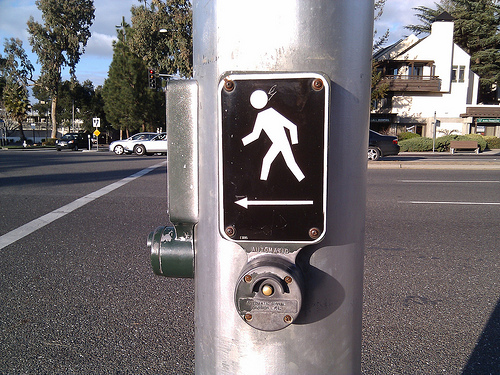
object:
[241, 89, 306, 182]
figure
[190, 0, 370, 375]
pole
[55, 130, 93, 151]
car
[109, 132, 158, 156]
car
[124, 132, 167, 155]
car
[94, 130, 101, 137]
traffic sign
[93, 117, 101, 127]
traffic sign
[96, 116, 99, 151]
pole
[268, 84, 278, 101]
writing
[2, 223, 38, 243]
paint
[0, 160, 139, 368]
ground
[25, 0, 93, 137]
trees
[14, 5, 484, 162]
back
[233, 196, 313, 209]
arrow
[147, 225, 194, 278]
light switch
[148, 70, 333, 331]
traffic equipment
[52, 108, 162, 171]
traffic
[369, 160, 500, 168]
curb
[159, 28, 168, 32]
street light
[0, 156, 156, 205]
area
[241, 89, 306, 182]
symbol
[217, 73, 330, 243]
crosswalk sign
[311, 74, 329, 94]
screw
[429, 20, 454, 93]
chimney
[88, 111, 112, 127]
road sign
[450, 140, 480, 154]
bench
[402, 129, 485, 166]
bus stop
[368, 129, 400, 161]
cars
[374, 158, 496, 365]
street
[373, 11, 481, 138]
house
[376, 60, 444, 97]
balcony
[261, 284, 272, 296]
button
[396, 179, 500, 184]
median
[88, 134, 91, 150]
pole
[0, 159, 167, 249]
line